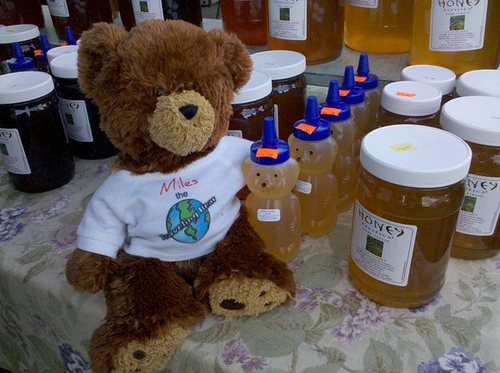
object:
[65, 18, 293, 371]
bear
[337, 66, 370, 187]
plastic bottle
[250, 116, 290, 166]
lid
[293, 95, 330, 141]
lid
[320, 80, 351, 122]
lid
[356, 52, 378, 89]
lid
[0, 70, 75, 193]
honey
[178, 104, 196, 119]
nose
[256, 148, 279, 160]
tag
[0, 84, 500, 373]
table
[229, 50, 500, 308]
honey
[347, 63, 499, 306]
jars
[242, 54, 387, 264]
bottles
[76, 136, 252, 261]
shirt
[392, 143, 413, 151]
sticker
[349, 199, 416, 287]
white label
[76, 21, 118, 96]
ear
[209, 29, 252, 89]
ear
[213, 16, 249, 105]
ear bear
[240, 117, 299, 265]
bottle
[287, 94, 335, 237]
bottle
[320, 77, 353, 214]
bottle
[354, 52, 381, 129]
bottle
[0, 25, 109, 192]
honey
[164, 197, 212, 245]
globe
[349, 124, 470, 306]
honey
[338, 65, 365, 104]
squeeze top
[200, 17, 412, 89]
shelf